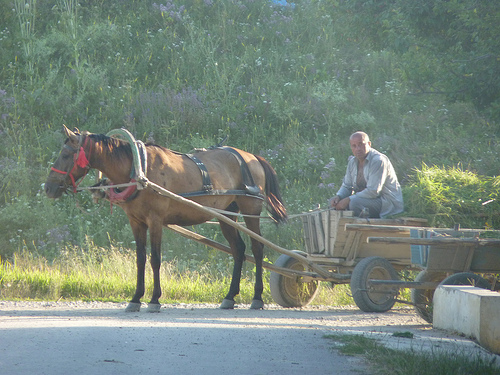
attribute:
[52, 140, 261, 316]
horse — brown, standing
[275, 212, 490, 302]
buggy — solid, wooden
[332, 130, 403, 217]
man — looking, bald, sitting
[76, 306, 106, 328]
road — flat, gravel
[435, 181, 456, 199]
grass — green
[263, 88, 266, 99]
flowers — wild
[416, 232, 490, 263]
cart — wooden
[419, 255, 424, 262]
planks — wood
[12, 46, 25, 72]
bushes — green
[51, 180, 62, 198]
mouth — closed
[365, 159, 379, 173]
shirt — unguttoned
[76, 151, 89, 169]
bridle — red